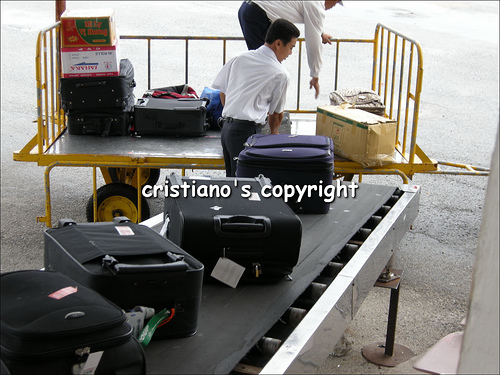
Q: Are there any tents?
A: No, there are no tents.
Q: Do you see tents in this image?
A: No, there are no tents.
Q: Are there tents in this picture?
A: No, there are no tents.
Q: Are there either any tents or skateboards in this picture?
A: No, there are no tents or skateboards.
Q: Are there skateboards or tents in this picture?
A: No, there are no tents or skateboards.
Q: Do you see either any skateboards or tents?
A: No, there are no tents or skateboards.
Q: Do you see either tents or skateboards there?
A: No, there are no tents or skateboards.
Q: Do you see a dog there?
A: No, there are no dogs.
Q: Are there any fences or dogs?
A: No, there are no dogs or fences.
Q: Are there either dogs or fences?
A: No, there are no dogs or fences.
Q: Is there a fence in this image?
A: No, there are no fences.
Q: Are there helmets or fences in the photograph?
A: No, there are no fences or helmets.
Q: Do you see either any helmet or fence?
A: No, there are no fences or helmets.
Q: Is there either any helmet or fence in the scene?
A: No, there are no fences or helmets.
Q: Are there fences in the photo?
A: No, there are no fences.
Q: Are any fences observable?
A: No, there are no fences.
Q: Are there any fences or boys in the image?
A: No, there are no fences or boys.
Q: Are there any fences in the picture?
A: No, there are no fences.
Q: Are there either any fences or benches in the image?
A: No, there are no fences or benches.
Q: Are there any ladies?
A: No, there are no ladies.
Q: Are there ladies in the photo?
A: No, there are no ladies.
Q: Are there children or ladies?
A: No, there are no ladies or children.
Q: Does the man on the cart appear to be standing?
A: Yes, the man is standing.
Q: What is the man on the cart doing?
A: The man is standing.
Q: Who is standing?
A: The man is standing.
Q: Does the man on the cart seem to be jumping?
A: No, the man is standing.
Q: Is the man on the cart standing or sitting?
A: The man is standing.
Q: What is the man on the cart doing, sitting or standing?
A: The man is standing.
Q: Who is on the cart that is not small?
A: The man is on the cart.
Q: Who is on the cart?
A: The man is on the cart.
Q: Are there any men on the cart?
A: Yes, there is a man on the cart.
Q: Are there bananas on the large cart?
A: No, there is a man on the cart.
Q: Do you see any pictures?
A: No, there are no pictures.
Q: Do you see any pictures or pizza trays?
A: No, there are no pictures or pizza trays.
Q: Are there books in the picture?
A: No, there are no books.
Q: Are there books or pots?
A: No, there are no books or pots.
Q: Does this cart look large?
A: Yes, the cart is large.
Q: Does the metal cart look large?
A: Yes, the cart is large.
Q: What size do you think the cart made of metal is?
A: The cart is large.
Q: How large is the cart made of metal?
A: The cart is large.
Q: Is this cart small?
A: No, the cart is large.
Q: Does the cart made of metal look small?
A: No, the cart is large.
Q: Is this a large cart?
A: Yes, this is a large cart.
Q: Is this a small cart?
A: No, this is a large cart.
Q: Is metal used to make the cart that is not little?
A: Yes, the cart is made of metal.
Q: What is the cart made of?
A: The cart is made of metal.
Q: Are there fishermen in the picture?
A: No, there are no fishermen.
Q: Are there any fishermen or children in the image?
A: No, there are no fishermen or children.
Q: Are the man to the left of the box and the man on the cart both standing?
A: Yes, both the man and the man are standing.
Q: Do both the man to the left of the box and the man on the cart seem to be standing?
A: Yes, both the man and the man are standing.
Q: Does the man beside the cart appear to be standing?
A: Yes, the man is standing.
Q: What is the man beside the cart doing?
A: The man is standing.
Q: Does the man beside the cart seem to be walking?
A: No, the man is standing.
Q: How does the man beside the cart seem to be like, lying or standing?
A: The man is standing.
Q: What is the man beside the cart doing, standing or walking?
A: The man is standing.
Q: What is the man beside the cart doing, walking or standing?
A: The man is standing.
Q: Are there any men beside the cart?
A: Yes, there is a man beside the cart.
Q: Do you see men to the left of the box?
A: Yes, there is a man to the left of the box.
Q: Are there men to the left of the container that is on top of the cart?
A: Yes, there is a man to the left of the box.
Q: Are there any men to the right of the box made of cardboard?
A: No, the man is to the left of the box.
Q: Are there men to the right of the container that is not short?
A: No, the man is to the left of the box.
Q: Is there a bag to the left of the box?
A: No, there is a man to the left of the box.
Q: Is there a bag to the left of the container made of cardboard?
A: No, there is a man to the left of the box.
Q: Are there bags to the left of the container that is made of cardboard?
A: No, there is a man to the left of the box.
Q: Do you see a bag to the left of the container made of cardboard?
A: No, there is a man to the left of the box.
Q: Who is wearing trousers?
A: The man is wearing trousers.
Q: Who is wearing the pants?
A: The man is wearing trousers.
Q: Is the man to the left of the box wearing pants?
A: Yes, the man is wearing pants.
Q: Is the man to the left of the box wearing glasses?
A: No, the man is wearing pants.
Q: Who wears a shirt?
A: The man wears a shirt.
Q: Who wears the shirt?
A: The man wears a shirt.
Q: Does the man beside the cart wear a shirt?
A: Yes, the man wears a shirt.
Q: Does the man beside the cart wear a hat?
A: No, the man wears a shirt.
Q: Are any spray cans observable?
A: No, there are no spray cans.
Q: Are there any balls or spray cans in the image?
A: No, there are no spray cans or balls.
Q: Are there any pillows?
A: No, there are no pillows.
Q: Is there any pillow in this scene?
A: No, there are no pillows.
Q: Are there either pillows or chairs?
A: No, there are no pillows or chairs.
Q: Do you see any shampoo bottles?
A: No, there are no shampoo bottles.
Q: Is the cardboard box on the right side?
A: Yes, the box is on the right of the image.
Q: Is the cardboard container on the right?
A: Yes, the box is on the right of the image.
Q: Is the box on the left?
A: No, the box is on the right of the image.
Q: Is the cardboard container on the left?
A: No, the box is on the right of the image.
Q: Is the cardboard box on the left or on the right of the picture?
A: The box is on the right of the image.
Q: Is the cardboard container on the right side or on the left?
A: The box is on the right of the image.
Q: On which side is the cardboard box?
A: The box is on the right of the image.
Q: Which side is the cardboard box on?
A: The box is on the right of the image.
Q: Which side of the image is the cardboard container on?
A: The box is on the right of the image.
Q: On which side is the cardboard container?
A: The box is on the right of the image.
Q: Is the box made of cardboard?
A: Yes, the box is made of cardboard.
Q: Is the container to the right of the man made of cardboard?
A: Yes, the box is made of cardboard.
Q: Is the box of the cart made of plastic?
A: No, the box is made of cardboard.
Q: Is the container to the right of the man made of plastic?
A: No, the box is made of cardboard.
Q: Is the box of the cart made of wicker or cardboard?
A: The box is made of cardboard.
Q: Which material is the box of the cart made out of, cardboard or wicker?
A: The box is made of cardboard.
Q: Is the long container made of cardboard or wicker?
A: The box is made of cardboard.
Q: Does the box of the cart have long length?
A: Yes, the box is long.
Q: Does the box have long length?
A: Yes, the box is long.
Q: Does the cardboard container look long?
A: Yes, the box is long.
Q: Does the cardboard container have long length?
A: Yes, the box is long.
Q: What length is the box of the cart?
A: The box is long.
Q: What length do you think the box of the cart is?
A: The box is long.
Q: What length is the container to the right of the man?
A: The box is long.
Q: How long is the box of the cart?
A: The box is long.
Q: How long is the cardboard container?
A: The box is long.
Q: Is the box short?
A: No, the box is long.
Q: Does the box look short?
A: No, the box is long.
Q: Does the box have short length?
A: No, the box is long.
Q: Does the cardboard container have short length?
A: No, the box is long.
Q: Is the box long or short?
A: The box is long.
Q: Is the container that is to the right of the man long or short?
A: The box is long.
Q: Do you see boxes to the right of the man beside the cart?
A: Yes, there is a box to the right of the man.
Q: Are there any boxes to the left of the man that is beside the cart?
A: No, the box is to the right of the man.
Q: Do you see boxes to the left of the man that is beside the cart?
A: No, the box is to the right of the man.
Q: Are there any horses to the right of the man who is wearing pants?
A: No, there is a box to the right of the man.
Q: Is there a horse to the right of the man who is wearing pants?
A: No, there is a box to the right of the man.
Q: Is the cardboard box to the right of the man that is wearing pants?
A: Yes, the box is to the right of the man.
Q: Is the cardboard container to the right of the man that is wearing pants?
A: Yes, the box is to the right of the man.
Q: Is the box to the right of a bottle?
A: No, the box is to the right of the man.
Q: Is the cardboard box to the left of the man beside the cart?
A: No, the box is to the right of the man.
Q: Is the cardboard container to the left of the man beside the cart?
A: No, the box is to the right of the man.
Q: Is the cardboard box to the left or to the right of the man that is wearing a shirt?
A: The box is to the right of the man.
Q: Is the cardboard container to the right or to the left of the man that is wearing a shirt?
A: The box is to the right of the man.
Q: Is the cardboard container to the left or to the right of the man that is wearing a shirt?
A: The box is to the right of the man.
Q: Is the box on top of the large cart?
A: Yes, the box is on top of the cart.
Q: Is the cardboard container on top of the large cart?
A: Yes, the box is on top of the cart.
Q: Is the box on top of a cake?
A: No, the box is on top of the cart.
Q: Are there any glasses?
A: No, there are no glasses.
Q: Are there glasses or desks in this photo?
A: No, there are no glasses or desks.